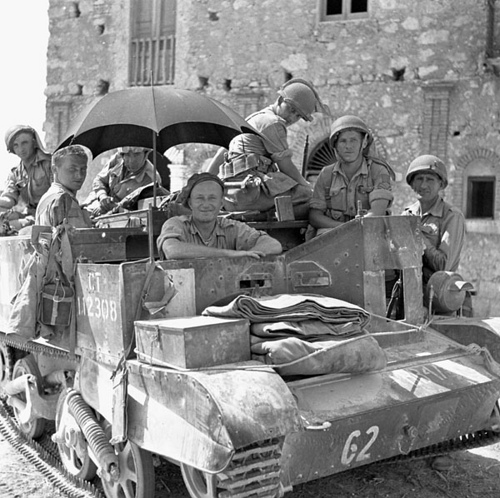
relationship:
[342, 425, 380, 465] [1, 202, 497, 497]
lettering on front of tank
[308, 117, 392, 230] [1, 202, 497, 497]
soldier riding on tank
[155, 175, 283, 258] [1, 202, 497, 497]
soldier riding on tank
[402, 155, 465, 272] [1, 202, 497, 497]
soldier riding on tank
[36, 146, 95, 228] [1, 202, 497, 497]
soldier riding on tank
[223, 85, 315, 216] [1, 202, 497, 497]
soldier riding on tank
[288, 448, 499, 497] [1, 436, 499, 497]
dirt on ground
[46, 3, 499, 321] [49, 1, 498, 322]
stone wall on building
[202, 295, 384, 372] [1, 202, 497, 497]
blankets on top of tank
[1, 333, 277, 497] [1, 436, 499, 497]
tank treads on ground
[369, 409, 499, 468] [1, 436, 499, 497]
tank treads on ground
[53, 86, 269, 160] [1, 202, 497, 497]
unbrella over tank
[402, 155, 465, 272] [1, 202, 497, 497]
soldier standing near tank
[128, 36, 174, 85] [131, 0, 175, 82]
wood bars over window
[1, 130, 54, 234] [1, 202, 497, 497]
soldier on a tank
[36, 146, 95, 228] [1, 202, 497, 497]
soldier on a tank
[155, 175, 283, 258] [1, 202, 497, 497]
soldier on a tank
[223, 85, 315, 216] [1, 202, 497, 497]
soldier on a tank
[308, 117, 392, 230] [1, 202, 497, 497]
soldier on a tank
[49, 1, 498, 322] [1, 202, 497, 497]
building near tank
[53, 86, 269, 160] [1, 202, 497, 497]
umbrella over tank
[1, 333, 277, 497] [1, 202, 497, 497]
tank treads under tank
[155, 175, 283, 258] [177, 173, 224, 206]
soldier wearing hat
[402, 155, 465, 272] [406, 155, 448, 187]
soldier wearing helmet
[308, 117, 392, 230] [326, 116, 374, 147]
soldier wearing helmet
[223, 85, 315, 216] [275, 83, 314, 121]
soldier wearing helmet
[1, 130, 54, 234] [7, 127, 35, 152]
soldier wearing helmet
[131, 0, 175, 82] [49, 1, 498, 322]
window on building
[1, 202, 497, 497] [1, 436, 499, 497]
tank on ground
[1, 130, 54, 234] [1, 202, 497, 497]
soldier riding on tank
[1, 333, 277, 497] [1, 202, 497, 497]
tank treads on tank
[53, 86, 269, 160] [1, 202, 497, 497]
unbrella on top of tank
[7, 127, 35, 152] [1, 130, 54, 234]
helmet on soldier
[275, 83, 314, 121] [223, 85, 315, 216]
helmet on soldier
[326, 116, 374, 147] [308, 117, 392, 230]
helmet on soldier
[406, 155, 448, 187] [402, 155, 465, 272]
helmet on soldier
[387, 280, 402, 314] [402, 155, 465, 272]
gun barrel near soldier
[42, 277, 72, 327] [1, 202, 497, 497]
canteen on side of tank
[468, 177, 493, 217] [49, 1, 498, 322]
window on building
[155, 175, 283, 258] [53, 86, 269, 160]
soldier sitting under umbrella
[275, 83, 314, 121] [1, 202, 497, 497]
helmet over tank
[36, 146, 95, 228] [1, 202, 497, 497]
soldier riding tank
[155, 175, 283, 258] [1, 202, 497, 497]
soldier riding tank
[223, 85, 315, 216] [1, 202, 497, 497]
soldier riding tank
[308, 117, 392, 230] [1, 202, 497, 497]
soldier riding tank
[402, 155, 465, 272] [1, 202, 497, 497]
soldier riding tank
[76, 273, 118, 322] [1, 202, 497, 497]
lettering on tank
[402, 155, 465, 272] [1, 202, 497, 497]
soldier on tank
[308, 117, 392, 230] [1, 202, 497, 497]
soldier on tank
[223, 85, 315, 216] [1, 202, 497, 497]
soldier on tank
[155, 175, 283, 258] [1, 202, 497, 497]
soldier on tank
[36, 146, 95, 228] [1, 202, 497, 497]
soldier on tank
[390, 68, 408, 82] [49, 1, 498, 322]
hole in building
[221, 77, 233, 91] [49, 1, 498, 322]
hole in building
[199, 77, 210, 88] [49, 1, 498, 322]
hole in building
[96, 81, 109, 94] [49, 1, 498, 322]
hole in building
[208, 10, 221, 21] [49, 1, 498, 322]
hole in building